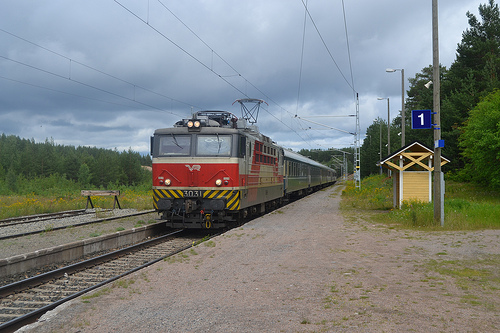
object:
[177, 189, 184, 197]
yellow stripes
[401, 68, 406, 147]
lamp post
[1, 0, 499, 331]
scene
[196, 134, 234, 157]
windows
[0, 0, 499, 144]
clouds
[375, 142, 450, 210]
building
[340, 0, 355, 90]
wires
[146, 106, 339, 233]
train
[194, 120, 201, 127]
train headlights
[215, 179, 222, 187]
headlight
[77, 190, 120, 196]
rail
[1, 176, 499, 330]
ground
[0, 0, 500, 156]
sky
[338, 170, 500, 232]
grass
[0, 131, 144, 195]
vegetation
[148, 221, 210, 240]
shadow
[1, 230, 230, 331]
tracks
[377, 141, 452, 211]
structure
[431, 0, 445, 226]
light post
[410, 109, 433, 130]
blue sign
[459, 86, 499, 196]
tree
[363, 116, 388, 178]
tree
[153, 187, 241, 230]
panel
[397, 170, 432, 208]
wooden pole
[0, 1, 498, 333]
photo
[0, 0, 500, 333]
outside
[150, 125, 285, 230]
engine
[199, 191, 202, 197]
number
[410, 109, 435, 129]
sign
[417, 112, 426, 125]
number 1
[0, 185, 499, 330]
dirt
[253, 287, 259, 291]
gravel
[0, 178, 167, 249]
part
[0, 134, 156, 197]
area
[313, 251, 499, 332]
part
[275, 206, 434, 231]
part